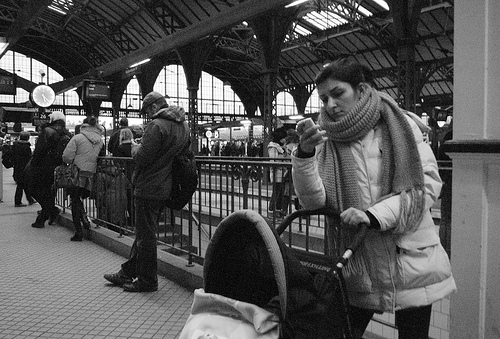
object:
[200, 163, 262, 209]
railing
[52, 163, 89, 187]
bag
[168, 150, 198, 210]
back pack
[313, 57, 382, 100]
hair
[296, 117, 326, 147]
cell phone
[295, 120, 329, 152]
hand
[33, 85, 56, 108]
clock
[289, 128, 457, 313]
jacket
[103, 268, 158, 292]
shoes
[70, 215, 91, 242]
shoes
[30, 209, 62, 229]
shoes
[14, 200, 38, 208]
shoes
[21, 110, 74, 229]
person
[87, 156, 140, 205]
wall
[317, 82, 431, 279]
scarf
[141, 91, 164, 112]
hat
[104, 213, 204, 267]
stairs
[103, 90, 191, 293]
man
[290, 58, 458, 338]
person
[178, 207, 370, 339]
stroller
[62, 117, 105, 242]
person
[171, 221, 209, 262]
underground